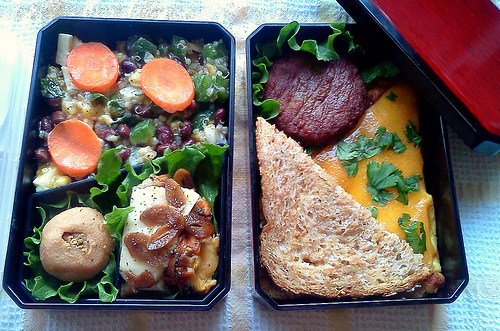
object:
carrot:
[66, 41, 120, 91]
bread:
[253, 116, 435, 301]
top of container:
[337, 0, 500, 156]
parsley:
[365, 160, 422, 207]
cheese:
[378, 101, 406, 135]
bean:
[120, 59, 139, 74]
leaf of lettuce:
[87, 147, 136, 237]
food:
[35, 173, 219, 304]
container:
[245, 23, 470, 311]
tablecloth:
[0, 301, 499, 330]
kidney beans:
[158, 126, 178, 155]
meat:
[263, 52, 368, 144]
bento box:
[2, 15, 237, 311]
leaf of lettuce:
[277, 20, 360, 61]